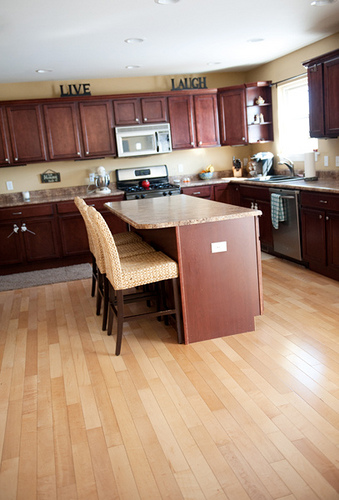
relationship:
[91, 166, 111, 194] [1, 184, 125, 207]
blender on a kitchen top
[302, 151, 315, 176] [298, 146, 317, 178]
roll of towels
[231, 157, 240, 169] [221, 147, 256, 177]
set of knives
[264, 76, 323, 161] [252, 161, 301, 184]
window behind sink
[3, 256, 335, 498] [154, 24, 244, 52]
surface of floor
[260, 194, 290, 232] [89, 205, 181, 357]
cloth seat of chair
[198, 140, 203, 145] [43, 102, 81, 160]
knob on door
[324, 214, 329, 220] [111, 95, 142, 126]
knob on door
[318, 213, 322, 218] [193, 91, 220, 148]
knob on door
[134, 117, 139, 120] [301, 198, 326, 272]
knob on door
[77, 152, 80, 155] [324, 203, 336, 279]
knob on door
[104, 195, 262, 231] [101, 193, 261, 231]
surface of counter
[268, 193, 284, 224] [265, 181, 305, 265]
towel hanging on dishwasher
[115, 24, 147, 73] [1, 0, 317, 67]
recessed lights in ceiling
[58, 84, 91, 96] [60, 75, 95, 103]
piece of art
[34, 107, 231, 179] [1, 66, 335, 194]
cabinets hung on wall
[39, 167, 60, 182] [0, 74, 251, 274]
sign hanging on wall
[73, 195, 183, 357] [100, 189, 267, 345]
chairs next to island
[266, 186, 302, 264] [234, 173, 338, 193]
dishwasher under counter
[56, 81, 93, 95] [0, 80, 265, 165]
live sitting atop of cabinet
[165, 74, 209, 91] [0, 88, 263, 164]
"laugh" sign sitting atop of cabinet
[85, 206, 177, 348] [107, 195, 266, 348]
chairs sitting at island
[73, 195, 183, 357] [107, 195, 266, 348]
chairs sitting at island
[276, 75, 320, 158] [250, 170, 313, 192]
window above sink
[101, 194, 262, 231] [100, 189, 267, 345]
counter attached to island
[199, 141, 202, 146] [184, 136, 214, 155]
knob attached to cabinet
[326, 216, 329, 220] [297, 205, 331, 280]
knob attached to cabinet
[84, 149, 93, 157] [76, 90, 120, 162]
knob attached to cabinet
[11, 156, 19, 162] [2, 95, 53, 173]
knob attached cabinet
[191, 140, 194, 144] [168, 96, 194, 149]
knob on cabinet